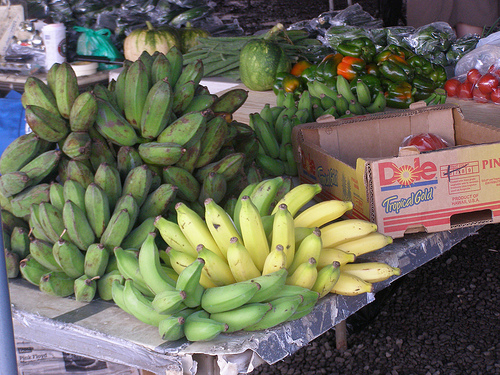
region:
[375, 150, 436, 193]
red Dole on side of box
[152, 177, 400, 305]
bunch of yellow bananas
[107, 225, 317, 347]
bunch of green bananas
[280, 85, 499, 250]
large square cardboard box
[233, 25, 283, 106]
spotted green bell pepper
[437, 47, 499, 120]
small ripe red tomatoes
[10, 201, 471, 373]
table top covered in plastic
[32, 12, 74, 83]
polystyrene take out coffee mug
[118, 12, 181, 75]
white and green pumpkin squash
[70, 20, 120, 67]
aqua blue gift ribbon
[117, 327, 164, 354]
edge of a table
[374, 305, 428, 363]
part of a cloud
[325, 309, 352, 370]
part of a stand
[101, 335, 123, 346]
edge of a table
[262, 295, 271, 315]
tip of a banana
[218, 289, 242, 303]
edge of a banana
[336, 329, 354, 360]
part of a banana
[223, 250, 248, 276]
part of a banana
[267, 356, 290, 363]
edge of a top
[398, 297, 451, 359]
part of a ground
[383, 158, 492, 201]
this is a box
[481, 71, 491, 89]
this is a tomato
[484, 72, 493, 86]
the tomato is red in color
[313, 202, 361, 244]
this is a banana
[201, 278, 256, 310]
the banana is green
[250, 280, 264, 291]
this is the tip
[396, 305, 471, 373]
this is the floor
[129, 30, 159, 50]
this is a calabas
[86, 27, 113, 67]
this is a paper bag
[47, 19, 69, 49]
this is a container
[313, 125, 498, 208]
this is a box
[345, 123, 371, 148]
the box is made of carton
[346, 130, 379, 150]
the box is brown in color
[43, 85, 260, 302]
these are bunches of bananas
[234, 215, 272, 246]
the bananas are yellow in color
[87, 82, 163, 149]
the bananas are green in color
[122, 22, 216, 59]
these are two pumpkins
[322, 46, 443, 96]
these are some vegetables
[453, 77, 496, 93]
these are some tomatoes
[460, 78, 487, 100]
the tomatoes are red in color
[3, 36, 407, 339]
green bananas on a table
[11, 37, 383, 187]
green handles of bananas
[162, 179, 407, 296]
a handle of yellow bananas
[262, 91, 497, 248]
a cardboard box on a table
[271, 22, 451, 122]
green peppers next to bananas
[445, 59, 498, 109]
red tomatoes on box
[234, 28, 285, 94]
a watermelon next to peppers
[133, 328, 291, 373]
corner of table is broken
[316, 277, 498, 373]
gravel below a table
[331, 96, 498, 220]
a red pepper in a cardboard box